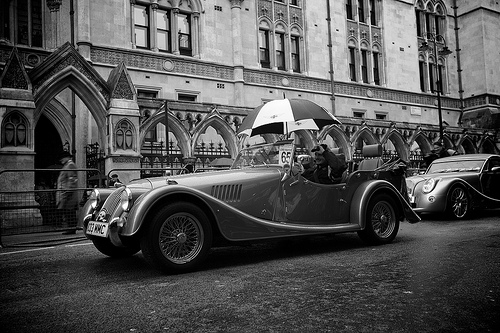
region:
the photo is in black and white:
[57, 20, 457, 216]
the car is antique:
[90, 168, 482, 249]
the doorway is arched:
[16, 63, 115, 169]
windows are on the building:
[101, 7, 352, 70]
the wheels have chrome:
[145, 212, 230, 299]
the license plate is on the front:
[75, 212, 122, 244]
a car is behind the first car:
[399, 158, 491, 230]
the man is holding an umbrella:
[226, 86, 449, 164]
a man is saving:
[295, 130, 397, 216]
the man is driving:
[268, 137, 475, 245]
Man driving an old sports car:
[75, 124, 422, 273]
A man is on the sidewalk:
[49, 148, 81, 233]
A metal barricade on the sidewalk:
[6, 163, 103, 233]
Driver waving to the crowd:
[302, 139, 345, 184]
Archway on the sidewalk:
[5, 45, 145, 228]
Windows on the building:
[253, 22, 304, 74]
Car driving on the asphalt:
[77, 137, 427, 282]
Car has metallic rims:
[151, 205, 211, 275]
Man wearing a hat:
[53, 145, 74, 158]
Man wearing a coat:
[55, 160, 78, 212]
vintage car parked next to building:
[71, 131, 426, 270]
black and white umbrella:
[231, 94, 345, 141]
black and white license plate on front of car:
[81, 217, 114, 240]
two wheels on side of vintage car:
[152, 188, 409, 271]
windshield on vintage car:
[230, 138, 297, 170]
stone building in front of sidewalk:
[3, 0, 498, 230]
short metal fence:
[1, 185, 96, 235]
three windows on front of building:
[256, 22, 306, 73]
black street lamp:
[414, 30, 470, 155]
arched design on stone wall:
[137, 103, 198, 166]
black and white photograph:
[30, 15, 478, 292]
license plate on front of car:
[75, 213, 112, 242]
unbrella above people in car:
[234, 88, 334, 148]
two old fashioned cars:
[77, 119, 498, 262]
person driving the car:
[301, 138, 339, 182]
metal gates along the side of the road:
[2, 161, 102, 234]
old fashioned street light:
[410, 28, 460, 150]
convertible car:
[87, 99, 412, 269]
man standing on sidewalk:
[51, 145, 80, 231]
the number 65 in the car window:
[274, 133, 299, 177]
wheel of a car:
[144, 197, 216, 273]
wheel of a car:
[359, 189, 404, 249]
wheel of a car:
[444, 183, 470, 223]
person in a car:
[306, 140, 343, 185]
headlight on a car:
[115, 184, 131, 213]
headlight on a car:
[87, 186, 101, 210]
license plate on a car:
[79, 218, 111, 235]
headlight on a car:
[420, 175, 435, 192]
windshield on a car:
[422, 152, 492, 177]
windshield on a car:
[229, 140, 296, 170]